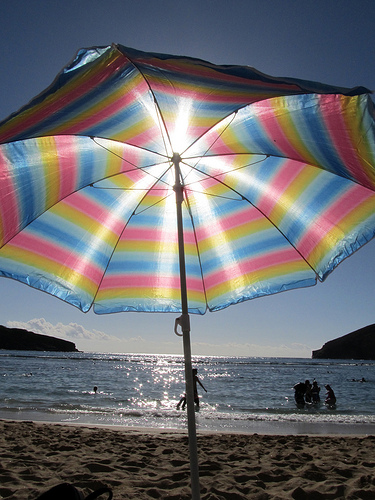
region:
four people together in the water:
[287, 375, 340, 409]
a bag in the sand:
[13, 469, 113, 499]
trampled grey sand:
[1, 414, 372, 498]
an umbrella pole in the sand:
[167, 285, 209, 491]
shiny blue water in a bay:
[2, 346, 373, 424]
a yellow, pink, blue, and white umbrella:
[2, 2, 370, 314]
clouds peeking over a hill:
[7, 313, 120, 355]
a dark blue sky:
[8, 7, 373, 105]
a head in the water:
[90, 383, 100, 392]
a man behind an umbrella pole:
[187, 364, 207, 410]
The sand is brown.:
[17, 431, 157, 493]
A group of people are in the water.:
[262, 373, 351, 419]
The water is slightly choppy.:
[32, 361, 80, 394]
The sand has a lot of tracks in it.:
[36, 437, 165, 490]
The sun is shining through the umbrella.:
[76, 77, 265, 308]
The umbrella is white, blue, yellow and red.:
[2, 43, 371, 306]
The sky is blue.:
[231, 3, 364, 54]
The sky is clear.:
[240, 3, 365, 60]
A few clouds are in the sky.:
[80, 325, 122, 341]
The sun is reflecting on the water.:
[123, 359, 183, 378]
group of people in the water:
[278, 372, 366, 414]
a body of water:
[36, 353, 181, 389]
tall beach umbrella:
[1, 34, 367, 495]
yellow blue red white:
[6, 38, 367, 295]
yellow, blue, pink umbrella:
[6, 27, 374, 336]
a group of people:
[269, 372, 356, 449]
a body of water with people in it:
[207, 355, 371, 437]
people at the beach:
[199, 338, 372, 493]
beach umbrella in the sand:
[54, 7, 347, 498]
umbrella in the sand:
[8, 53, 295, 491]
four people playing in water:
[289, 377, 337, 415]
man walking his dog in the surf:
[175, 364, 206, 414]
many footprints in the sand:
[3, 422, 372, 498]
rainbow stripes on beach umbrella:
[2, 49, 372, 309]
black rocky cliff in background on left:
[0, 318, 89, 355]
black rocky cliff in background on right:
[309, 319, 373, 361]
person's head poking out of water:
[88, 383, 103, 394]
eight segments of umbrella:
[90, 97, 268, 222]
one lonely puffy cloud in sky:
[4, 313, 124, 345]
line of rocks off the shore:
[3, 351, 369, 371]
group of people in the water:
[282, 375, 354, 416]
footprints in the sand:
[220, 452, 335, 487]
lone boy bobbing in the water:
[85, 379, 101, 394]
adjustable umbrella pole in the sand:
[169, 182, 207, 490]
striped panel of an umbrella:
[177, 158, 323, 325]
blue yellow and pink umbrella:
[6, 38, 349, 325]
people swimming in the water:
[278, 366, 366, 413]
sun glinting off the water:
[144, 362, 174, 413]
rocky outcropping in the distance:
[5, 317, 87, 365]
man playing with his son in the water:
[177, 366, 216, 418]